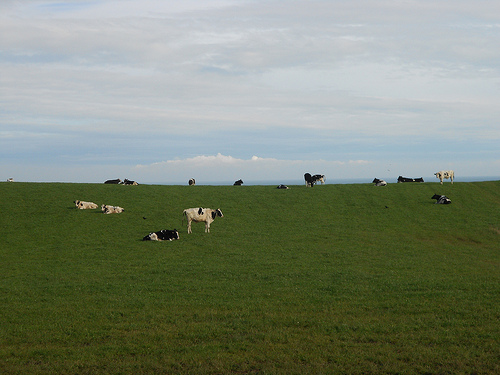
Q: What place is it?
A: It is a field.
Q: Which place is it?
A: It is a field.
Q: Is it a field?
A: Yes, it is a field.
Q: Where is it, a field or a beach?
A: It is a field.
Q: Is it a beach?
A: No, it is a field.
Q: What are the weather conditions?
A: It is cloudy.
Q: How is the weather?
A: It is cloudy.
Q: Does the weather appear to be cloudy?
A: Yes, it is cloudy.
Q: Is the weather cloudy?
A: Yes, it is cloudy.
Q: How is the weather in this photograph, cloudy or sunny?
A: It is cloudy.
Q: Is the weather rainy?
A: No, it is cloudy.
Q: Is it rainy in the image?
A: No, it is cloudy.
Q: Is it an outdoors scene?
A: Yes, it is outdoors.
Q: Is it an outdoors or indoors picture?
A: It is outdoors.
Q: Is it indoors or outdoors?
A: It is outdoors.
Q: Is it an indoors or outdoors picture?
A: It is outdoors.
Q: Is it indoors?
A: No, it is outdoors.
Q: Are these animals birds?
A: No, there are both birds and cows.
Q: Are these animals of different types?
A: Yes, they are birds and cows.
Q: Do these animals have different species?
A: Yes, they are birds and cows.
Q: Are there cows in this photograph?
A: Yes, there are cows.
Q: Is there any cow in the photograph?
A: Yes, there are cows.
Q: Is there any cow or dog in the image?
A: Yes, there are cows.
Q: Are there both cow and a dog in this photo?
A: No, there are cows but no dogs.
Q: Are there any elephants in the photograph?
A: No, there are no elephants.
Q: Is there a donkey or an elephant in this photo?
A: No, there are no elephants or donkeys.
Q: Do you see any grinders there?
A: No, there are no grinders.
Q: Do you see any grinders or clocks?
A: No, there are no grinders or clocks.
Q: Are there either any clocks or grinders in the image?
A: No, there are no grinders or clocks.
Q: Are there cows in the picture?
A: Yes, there are cows.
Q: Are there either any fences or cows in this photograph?
A: Yes, there are cows.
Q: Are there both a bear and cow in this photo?
A: No, there are cows but no bears.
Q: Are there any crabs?
A: No, there are no crabs.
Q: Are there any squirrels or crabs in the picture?
A: No, there are no crabs or squirrels.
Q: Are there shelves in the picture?
A: No, there are no shelves.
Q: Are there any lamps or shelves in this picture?
A: No, there are no shelves or lamps.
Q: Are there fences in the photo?
A: No, there are no fences.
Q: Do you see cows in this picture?
A: Yes, there are cows.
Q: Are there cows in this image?
A: Yes, there are cows.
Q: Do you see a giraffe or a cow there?
A: Yes, there are cows.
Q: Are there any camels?
A: No, there are no camels.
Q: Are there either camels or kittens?
A: No, there are no camels or kittens.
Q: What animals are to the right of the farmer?
A: The animals are cows.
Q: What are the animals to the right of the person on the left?
A: The animals are cows.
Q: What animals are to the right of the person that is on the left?
A: The animals are cows.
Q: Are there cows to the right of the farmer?
A: Yes, there are cows to the right of the farmer.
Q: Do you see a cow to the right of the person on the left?
A: Yes, there are cows to the right of the farmer.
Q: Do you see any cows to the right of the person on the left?
A: Yes, there are cows to the right of the farmer.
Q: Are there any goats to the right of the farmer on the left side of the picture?
A: No, there are cows to the right of the farmer.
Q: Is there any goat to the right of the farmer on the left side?
A: No, there are cows to the right of the farmer.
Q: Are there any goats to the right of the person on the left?
A: No, there are cows to the right of the farmer.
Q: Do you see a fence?
A: No, there are no fences.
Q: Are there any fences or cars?
A: No, there are no fences or cars.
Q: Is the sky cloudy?
A: Yes, the sky is cloudy.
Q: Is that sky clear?
A: No, the sky is cloudy.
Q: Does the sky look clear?
A: No, the sky is cloudy.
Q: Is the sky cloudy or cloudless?
A: The sky is cloudy.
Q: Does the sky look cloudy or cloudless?
A: The sky is cloudy.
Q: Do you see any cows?
A: Yes, there is a cow.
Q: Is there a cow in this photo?
A: Yes, there is a cow.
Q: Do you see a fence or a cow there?
A: Yes, there is a cow.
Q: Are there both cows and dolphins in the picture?
A: No, there is a cow but no dolphins.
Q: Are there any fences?
A: No, there are no fences.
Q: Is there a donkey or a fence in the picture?
A: No, there are no fences or donkeys.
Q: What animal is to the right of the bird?
A: The animal is a cow.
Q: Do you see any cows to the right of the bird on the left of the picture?
A: Yes, there is a cow to the right of the bird.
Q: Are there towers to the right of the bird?
A: No, there is a cow to the right of the bird.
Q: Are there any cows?
A: Yes, there is a cow.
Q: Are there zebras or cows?
A: Yes, there is a cow.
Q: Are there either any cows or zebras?
A: Yes, there is a cow.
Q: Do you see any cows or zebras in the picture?
A: Yes, there is a cow.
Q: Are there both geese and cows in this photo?
A: No, there is a cow but no geese.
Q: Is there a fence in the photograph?
A: No, there are no fences.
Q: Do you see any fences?
A: No, there are no fences.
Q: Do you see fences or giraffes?
A: No, there are no fences or giraffes.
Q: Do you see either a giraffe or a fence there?
A: No, there are no fences or giraffes.